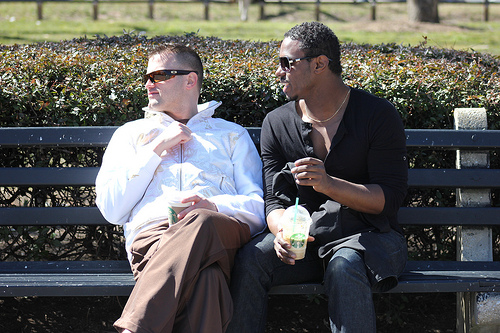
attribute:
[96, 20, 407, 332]
people — in the picture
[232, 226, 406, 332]
pants — black, blue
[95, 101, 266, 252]
jacket — white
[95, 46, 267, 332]
man — drinking, holding, sitting, caucasian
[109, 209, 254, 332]
pants — brown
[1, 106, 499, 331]
bench — wooden, sitting, sunny, woode, blue, stone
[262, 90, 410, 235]
shirt — black, v-neck, zip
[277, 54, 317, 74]
sunglasses — pair, black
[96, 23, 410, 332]
men — looking, sitting, in the picture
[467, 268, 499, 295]
wood — white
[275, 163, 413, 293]
jacket — black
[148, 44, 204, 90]
hair — short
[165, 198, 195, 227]
drink — frozen, empty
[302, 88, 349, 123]
necklace — worn